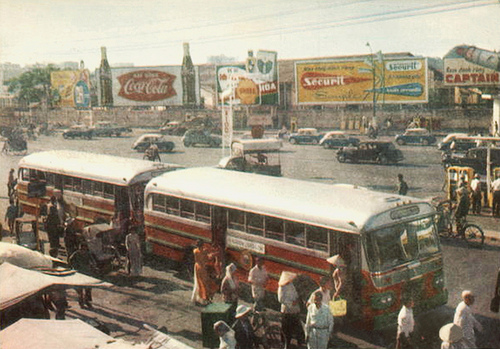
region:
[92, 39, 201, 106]
Big red and white Coca Cola billboard.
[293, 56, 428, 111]
Huge yellow Securit billboard.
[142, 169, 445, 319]
Red and white transit bus.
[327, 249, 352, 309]
Woman getting off bus.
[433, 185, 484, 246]
Man sitting on bike.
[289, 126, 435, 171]
Cars driving on street.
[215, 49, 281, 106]
Green, white, yellow, and red billboard.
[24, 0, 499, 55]
Power lines over street.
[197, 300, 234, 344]
Green newspaper stand.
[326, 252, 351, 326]
Woman wearing hat on head.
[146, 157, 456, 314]
a bus on the street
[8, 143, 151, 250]
bus behind another bus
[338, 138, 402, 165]
vehicle on the street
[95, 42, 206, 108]
advertisement on a building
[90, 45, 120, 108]
shape of beverage on advertisement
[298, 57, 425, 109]
an advertisement on building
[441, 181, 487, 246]
person on a bike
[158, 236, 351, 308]
people boarding and getting off bus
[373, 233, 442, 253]
front window to bus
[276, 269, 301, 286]
hat on person on street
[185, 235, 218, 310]
person standing near a bus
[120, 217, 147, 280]
person standing near a bus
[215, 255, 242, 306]
person standing near a bus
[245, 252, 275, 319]
person standing near a bus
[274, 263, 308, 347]
person standing near a bus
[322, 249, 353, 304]
person standing near a bus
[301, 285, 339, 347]
person standing near a bus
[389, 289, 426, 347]
person standing near a bus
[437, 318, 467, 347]
person standing near a bus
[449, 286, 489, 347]
person standing near a bus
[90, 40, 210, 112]
old-fashioned Coca Cola billboard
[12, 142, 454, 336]
red and green light rail train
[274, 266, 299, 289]
hat in the shape of a cone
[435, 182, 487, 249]
person on a bicycle in street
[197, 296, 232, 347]
green trash bin on sidewalk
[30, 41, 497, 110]
several billboards in a row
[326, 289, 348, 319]
yellow purse carried by lady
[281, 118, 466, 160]
cars in part of a parking lot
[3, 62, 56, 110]
tall tree by billboards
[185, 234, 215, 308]
lady in an orange dress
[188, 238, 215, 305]
A woman waiting to board a bus in a long white and orange dress.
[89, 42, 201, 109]
A Coca Cola billboard with two large bottles on each side.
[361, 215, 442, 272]
The large front windshield of a orange ane white bus.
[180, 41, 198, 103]
Large brown bottle to the right of the Coca Cola logo.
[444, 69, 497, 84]
The word CAPTAIN in big red letters.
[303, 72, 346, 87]
Securit in white letters on a billboard.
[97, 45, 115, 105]
A brown bottle to the left of the Coca Cola logo.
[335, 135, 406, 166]
A black car in the road under an orange billboard.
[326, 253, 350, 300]
A peson coming off the front of a bus in a pointy Chinese hat.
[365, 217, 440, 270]
Front large windshield of a bus.